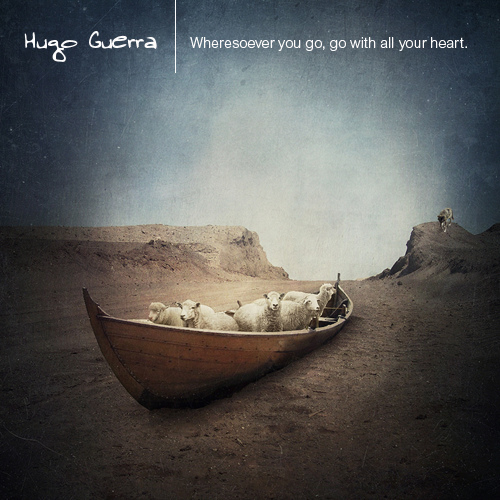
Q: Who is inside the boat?
A: Sheep.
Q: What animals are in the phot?
A: Sheep.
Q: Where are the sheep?
A: In a boat.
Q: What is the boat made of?
A: Wood.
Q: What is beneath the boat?
A: Sand.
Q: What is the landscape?
A: Desert.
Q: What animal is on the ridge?
A: A wolf.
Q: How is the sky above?
A: Clear.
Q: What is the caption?
A: A quote.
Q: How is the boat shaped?
A: Oval.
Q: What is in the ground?
A: Boat.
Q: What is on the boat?
A: Sheep.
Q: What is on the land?
A: Boat.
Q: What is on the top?
A: Text.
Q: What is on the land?
A: Sand.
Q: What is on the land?
A: Wooden boat.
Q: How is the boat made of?
A: Wood.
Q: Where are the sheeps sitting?
A: Boat.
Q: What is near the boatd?
A: Dirt.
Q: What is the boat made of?
A: Wood.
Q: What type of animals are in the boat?
A: Sheep.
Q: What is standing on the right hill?
A: An animal.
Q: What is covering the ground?
A: Dirt.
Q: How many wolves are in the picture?
A: One.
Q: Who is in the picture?
A: No one.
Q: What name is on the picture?
A: Hugo Guerra.